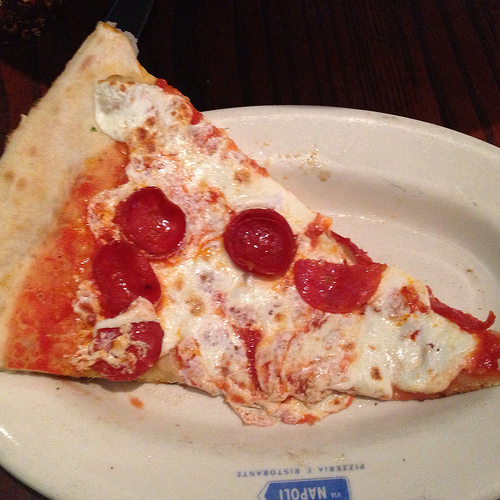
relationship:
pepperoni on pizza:
[94, 242, 159, 316] [1, 22, 500, 427]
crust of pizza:
[1, 16, 152, 333] [1, 22, 500, 427]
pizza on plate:
[1, 22, 500, 427] [3, 378, 498, 499]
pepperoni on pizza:
[297, 262, 384, 312] [1, 22, 500, 427]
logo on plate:
[261, 479, 349, 499] [3, 378, 498, 499]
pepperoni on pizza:
[94, 323, 164, 382] [1, 22, 500, 427]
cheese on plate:
[229, 392, 353, 427] [3, 378, 498, 499]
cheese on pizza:
[100, 84, 479, 424] [1, 22, 500, 427]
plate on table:
[3, 378, 498, 499] [139, 3, 499, 150]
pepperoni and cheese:
[228, 207, 295, 277] [229, 392, 353, 427]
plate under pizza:
[3, 378, 498, 499] [1, 22, 500, 427]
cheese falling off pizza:
[229, 392, 353, 427] [1, 22, 500, 427]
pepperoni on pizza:
[228, 207, 295, 277] [1, 22, 500, 427]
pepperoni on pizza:
[121, 185, 187, 255] [1, 22, 500, 427]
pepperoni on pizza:
[333, 231, 372, 266] [1, 22, 500, 427]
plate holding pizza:
[3, 378, 498, 499] [1, 22, 500, 427]